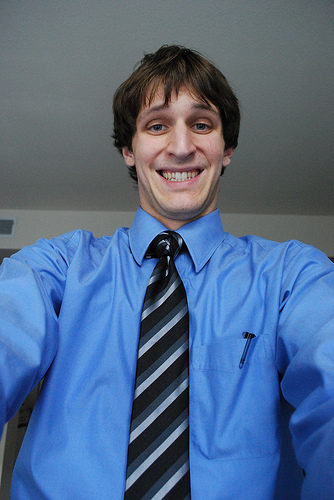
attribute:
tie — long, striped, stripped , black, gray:
[120, 226, 192, 498]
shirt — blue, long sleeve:
[0, 202, 333, 496]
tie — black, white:
[117, 222, 203, 498]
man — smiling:
[22, 28, 308, 299]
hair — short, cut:
[113, 47, 242, 182]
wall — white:
[209, 215, 333, 244]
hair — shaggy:
[109, 43, 240, 151]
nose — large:
[142, 115, 205, 171]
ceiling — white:
[2, 2, 330, 212]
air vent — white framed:
[3, 211, 18, 236]